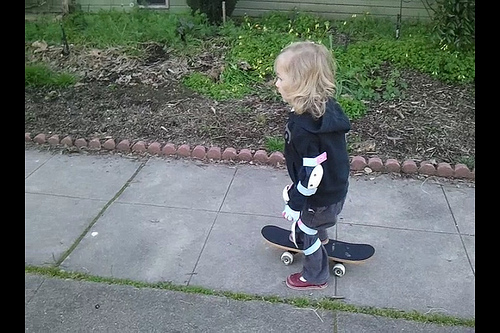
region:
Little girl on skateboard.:
[244, 35, 382, 294]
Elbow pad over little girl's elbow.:
[295, 155, 325, 195]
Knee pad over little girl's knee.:
[288, 214, 323, 259]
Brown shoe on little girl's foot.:
[280, 265, 330, 292]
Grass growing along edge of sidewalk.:
[48, 263, 260, 312]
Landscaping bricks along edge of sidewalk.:
[58, 130, 268, 169]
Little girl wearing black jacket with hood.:
[276, 98, 356, 212]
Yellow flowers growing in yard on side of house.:
[236, 19, 343, 80]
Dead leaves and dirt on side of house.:
[73, 43, 258, 145]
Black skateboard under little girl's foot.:
[253, 213, 394, 276]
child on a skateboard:
[235, 12, 415, 305]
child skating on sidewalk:
[55, 10, 451, 320]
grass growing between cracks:
[95, 265, 160, 330]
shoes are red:
[270, 241, 377, 302]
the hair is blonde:
[220, 31, 436, 302]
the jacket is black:
[226, 22, 406, 297]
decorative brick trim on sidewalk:
[80, 93, 242, 210]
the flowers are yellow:
[170, 38, 290, 126]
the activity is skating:
[205, 15, 426, 330]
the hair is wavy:
[242, 10, 407, 300]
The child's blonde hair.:
[280, 48, 340, 108]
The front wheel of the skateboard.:
[279, 246, 292, 266]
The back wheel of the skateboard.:
[330, 263, 347, 280]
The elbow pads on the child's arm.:
[300, 155, 321, 201]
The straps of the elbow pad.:
[299, 149, 327, 201]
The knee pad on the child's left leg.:
[291, 223, 319, 253]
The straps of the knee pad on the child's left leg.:
[297, 216, 324, 261]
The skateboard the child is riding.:
[258, 223, 383, 280]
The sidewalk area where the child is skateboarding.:
[149, 169, 497, 301]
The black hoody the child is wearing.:
[283, 106, 345, 205]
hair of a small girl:
[304, 78, 329, 98]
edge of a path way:
[168, 222, 209, 234]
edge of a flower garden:
[201, 132, 224, 164]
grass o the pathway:
[150, 283, 202, 295]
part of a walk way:
[151, 229, 195, 234]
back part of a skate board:
[358, 248, 360, 255]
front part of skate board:
[268, 227, 275, 235]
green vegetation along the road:
[413, 43, 432, 60]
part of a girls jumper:
[321, 122, 334, 137]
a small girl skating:
[276, 61, 321, 251]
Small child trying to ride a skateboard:
[259, 40, 376, 294]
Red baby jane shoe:
[285, 272, 324, 292]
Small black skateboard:
[256, 217, 376, 280]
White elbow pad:
[301, 158, 326, 198]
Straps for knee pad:
[288, 221, 321, 256]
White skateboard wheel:
[331, 260, 343, 278]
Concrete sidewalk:
[51, 156, 235, 291]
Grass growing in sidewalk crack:
[68, 262, 236, 302]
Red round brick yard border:
[51, 132, 218, 158]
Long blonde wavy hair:
[272, 38, 339, 118]